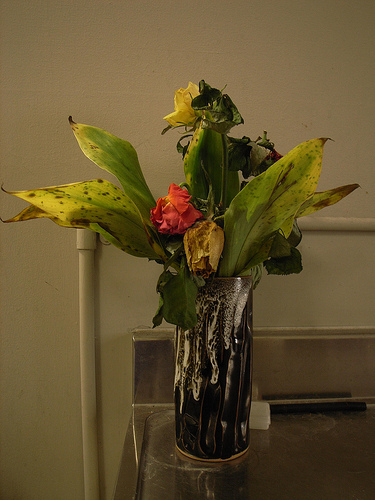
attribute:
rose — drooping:
[152, 183, 207, 234]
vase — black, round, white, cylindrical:
[174, 273, 252, 463]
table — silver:
[112, 326, 374, 499]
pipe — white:
[76, 227, 102, 500]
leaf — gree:
[220, 135, 332, 275]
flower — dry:
[2, 79, 360, 330]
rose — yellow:
[183, 219, 225, 275]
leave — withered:
[151, 273, 200, 328]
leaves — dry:
[224, 132, 270, 172]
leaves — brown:
[298, 180, 360, 224]